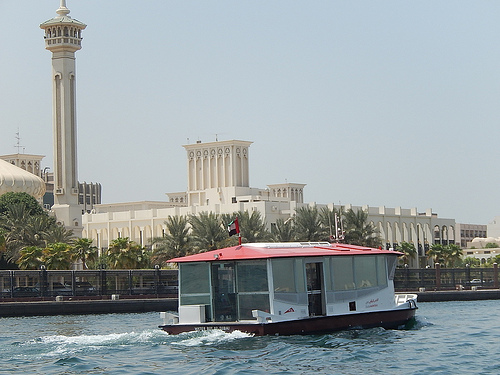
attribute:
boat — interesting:
[158, 216, 437, 363]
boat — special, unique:
[157, 215, 445, 347]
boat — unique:
[150, 207, 428, 356]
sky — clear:
[272, 5, 475, 168]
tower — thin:
[33, 0, 91, 232]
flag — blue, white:
[222, 207, 245, 247]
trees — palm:
[14, 237, 142, 264]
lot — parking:
[2, 273, 192, 303]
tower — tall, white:
[40, 0, 85, 240]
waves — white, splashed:
[36, 327, 253, 349]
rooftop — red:
[165, 238, 405, 261]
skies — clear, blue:
[102, 10, 497, 124]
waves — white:
[23, 332, 245, 362]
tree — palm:
[20, 223, 81, 288]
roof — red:
[166, 236, 409, 271]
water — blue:
[12, 302, 462, 364]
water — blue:
[30, 306, 464, 366]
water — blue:
[37, 303, 477, 370]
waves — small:
[444, 340, 471, 357]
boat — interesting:
[160, 218, 424, 353]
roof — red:
[165, 225, 413, 265]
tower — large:
[41, 12, 91, 293]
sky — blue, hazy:
[20, 28, 470, 210]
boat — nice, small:
[160, 226, 429, 337]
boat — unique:
[147, 224, 387, 311]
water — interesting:
[41, 305, 497, 362]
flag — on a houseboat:
[226, 214, 242, 246]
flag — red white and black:
[228, 212, 246, 249]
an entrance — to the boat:
[210, 259, 240, 325]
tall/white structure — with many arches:
[351, 204, 475, 264]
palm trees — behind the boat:
[13, 210, 235, 265]